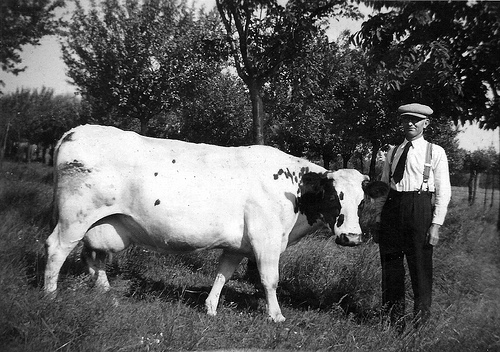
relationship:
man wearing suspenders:
[370, 102, 453, 325] [378, 141, 439, 326]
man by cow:
[370, 102, 453, 325] [43, 124, 390, 323]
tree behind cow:
[215, 0, 353, 145] [43, 124, 390, 323]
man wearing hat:
[370, 102, 453, 325] [397, 103, 434, 120]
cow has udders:
[43, 124, 390, 323] [84, 215, 134, 262]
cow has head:
[43, 124, 390, 323] [304, 169, 391, 246]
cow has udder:
[43, 124, 390, 323] [82, 218, 136, 265]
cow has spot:
[43, 124, 390, 323] [153, 199, 161, 208]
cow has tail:
[43, 124, 390, 323] [48, 126, 79, 237]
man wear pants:
[370, 102, 453, 325] [380, 187, 438, 331]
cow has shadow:
[43, 124, 390, 323] [25, 250, 386, 323]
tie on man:
[391, 141, 413, 183] [370, 102, 453, 325]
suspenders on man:
[378, 141, 439, 326] [370, 102, 453, 325]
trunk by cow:
[216, 0, 344, 146] [43, 124, 390, 323]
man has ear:
[370, 102, 453, 325] [423, 118, 432, 130]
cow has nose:
[43, 124, 390, 323] [336, 233, 367, 246]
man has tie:
[370, 102, 453, 325] [391, 141, 413, 183]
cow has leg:
[43, 124, 390, 323] [43, 224, 82, 296]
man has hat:
[370, 102, 453, 325] [397, 103, 434, 120]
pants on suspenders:
[380, 187, 438, 331] [378, 141, 439, 326]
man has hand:
[370, 102, 453, 325] [427, 223, 443, 246]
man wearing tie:
[370, 102, 453, 325] [391, 141, 413, 183]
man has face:
[370, 102, 453, 325] [400, 116, 431, 142]